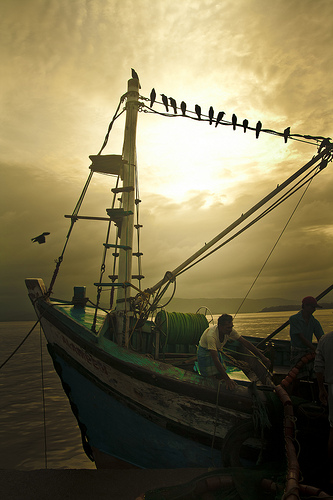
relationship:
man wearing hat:
[288, 291, 325, 358] [301, 293, 322, 309]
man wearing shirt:
[192, 309, 270, 380] [199, 326, 243, 351]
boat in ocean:
[27, 63, 332, 467] [4, 312, 333, 470]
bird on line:
[150, 88, 157, 107] [138, 92, 324, 145]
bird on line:
[160, 91, 169, 112] [138, 92, 324, 145]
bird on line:
[253, 119, 265, 138] [138, 92, 324, 145]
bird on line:
[230, 111, 239, 133] [138, 92, 324, 145]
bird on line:
[281, 122, 291, 145] [138, 92, 324, 145]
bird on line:
[191, 102, 203, 122] [138, 92, 324, 145]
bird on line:
[179, 95, 189, 116] [138, 92, 324, 145]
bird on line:
[206, 104, 214, 125] [138, 92, 324, 145]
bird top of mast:
[129, 65, 142, 90] [111, 77, 142, 342]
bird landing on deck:
[29, 229, 56, 245] [50, 296, 331, 382]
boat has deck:
[27, 63, 332, 467] [50, 296, 331, 382]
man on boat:
[288, 291, 325, 358] [27, 63, 332, 467]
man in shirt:
[192, 309, 270, 380] [199, 326, 243, 351]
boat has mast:
[27, 63, 332, 467] [111, 77, 142, 342]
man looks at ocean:
[288, 291, 325, 358] [4, 312, 333, 470]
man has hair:
[192, 309, 270, 380] [216, 311, 235, 327]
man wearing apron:
[192, 309, 270, 380] [195, 346, 227, 379]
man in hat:
[288, 291, 325, 358] [301, 293, 322, 309]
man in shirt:
[288, 291, 325, 358] [288, 314, 323, 339]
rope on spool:
[170, 308, 207, 342] [150, 305, 217, 360]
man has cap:
[288, 291, 325, 358] [301, 293, 322, 309]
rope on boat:
[170, 308, 207, 342] [27, 63, 332, 467]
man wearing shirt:
[288, 291, 325, 358] [288, 314, 323, 339]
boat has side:
[27, 63, 332, 467] [39, 311, 241, 467]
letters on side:
[59, 333, 110, 377] [39, 311, 241, 467]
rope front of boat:
[2, 319, 42, 369] [27, 63, 332, 467]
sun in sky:
[133, 71, 291, 206] [2, 1, 331, 311]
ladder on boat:
[95, 168, 133, 322] [27, 63, 332, 467]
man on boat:
[192, 309, 270, 380] [27, 63, 332, 467]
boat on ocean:
[27, 63, 332, 467] [4, 312, 333, 470]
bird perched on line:
[253, 119, 265, 138] [138, 92, 324, 145]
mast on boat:
[111, 77, 142, 342] [27, 63, 332, 467]